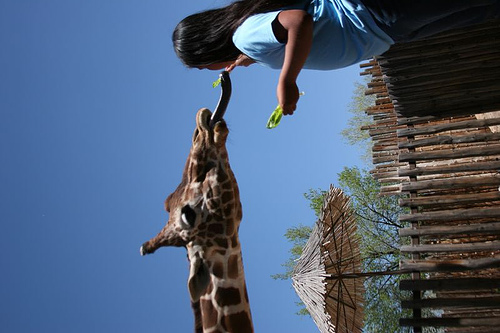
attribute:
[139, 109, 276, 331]
giraffe — brown, here, eating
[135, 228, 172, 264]
horns — brown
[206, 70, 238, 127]
tongue — long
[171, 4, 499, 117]
girl — feeding, here, eating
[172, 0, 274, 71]
hair — black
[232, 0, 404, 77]
shirt — blue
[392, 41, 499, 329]
fence — running across, wood, brown, wooden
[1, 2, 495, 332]
photo — sideways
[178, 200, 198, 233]
eye — black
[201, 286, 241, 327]
spots — brown, white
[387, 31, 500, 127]
shade — here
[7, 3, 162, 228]
sky — clear, blue